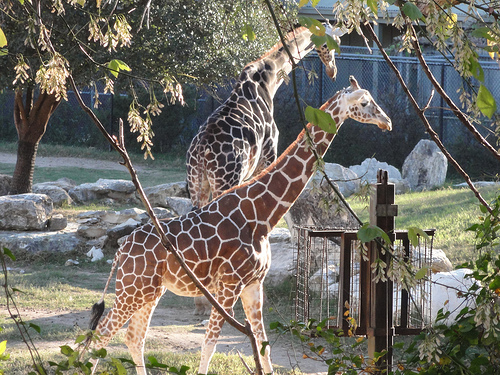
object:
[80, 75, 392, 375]
giraffe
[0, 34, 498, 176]
fences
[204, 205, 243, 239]
spots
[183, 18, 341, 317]
giraffe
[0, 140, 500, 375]
ground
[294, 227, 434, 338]
cage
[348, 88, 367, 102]
ear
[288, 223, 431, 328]
wire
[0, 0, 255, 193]
tree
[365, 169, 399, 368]
post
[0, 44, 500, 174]
fence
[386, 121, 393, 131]
nose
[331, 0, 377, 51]
leaves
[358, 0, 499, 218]
branches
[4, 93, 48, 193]
trunk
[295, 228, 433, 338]
feeder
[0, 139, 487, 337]
rocks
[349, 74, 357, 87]
horns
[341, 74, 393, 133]
head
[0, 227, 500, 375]
path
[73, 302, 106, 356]
hair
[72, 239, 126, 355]
tail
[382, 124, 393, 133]
mouth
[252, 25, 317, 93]
neck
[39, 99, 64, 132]
branch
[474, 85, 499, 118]
leaf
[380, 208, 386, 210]
nail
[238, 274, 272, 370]
leg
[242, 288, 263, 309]
patches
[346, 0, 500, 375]
tree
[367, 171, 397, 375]
wood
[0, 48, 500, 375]
pasture